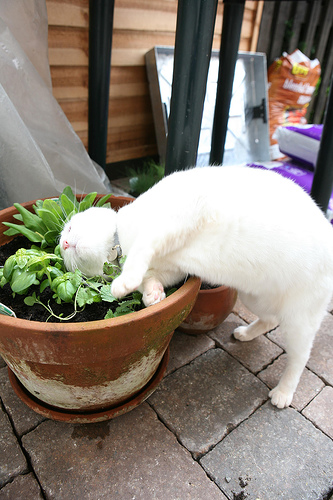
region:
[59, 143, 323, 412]
this is a cat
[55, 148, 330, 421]
the cat is white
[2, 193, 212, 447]
this is a potted plant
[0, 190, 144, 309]
the plant is green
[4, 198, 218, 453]
pot it terra cotta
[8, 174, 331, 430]
cat leaning on plant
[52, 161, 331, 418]
white cat with head in pot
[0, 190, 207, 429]
large terracotta flower pot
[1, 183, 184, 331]
green plants in flower pot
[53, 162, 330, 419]
cat rubbing head in plants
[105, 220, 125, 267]
gray collar on cat neck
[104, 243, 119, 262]
identification tag on collar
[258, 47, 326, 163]
orange bag of potting soil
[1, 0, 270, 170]
wood slat building siding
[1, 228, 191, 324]
soil in large pot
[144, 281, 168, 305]
pink cat toes on forepaw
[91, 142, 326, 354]
a white cat wearing a collar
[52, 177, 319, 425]
a white cat that is outside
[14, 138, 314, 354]
a white cat in a pot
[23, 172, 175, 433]
a pot with a plant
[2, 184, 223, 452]
a plant in a pot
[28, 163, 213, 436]
a plant that is outside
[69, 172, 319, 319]
a cat wearing a collar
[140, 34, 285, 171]
a pan that is outside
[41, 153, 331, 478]
a cat on a sidewalk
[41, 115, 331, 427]
The white cat is rubbing in the plants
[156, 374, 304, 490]
The patio has bricks on it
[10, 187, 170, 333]
There are plants in the flower pot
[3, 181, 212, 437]
The pot is made of clay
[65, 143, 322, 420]
The cat is completely white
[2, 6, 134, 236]
There is a plastic cover near the pot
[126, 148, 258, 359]
A smaller pot sits next to the cat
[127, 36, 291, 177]
A metal lid is leaned up against the wall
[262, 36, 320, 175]
A bag of soil is in the distance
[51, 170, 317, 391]
the cat is white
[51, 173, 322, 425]
the cat is white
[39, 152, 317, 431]
the cat is white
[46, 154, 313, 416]
the cat is white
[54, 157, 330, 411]
the cat is white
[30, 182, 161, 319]
cat's head on the plant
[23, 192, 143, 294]
cat's head on the plant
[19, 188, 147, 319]
cat's head on the plant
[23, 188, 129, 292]
cat's head on the plant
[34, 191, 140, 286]
cat's head on the plant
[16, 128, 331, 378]
A white short hair cat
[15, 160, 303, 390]
a cat loving a plant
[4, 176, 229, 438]
a potted green plant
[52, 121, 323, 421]
a cat only standing on hind feet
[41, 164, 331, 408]
Cat with his head in a planter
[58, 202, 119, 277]
White head of a cat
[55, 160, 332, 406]
an all white cat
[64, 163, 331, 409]
a cat standing on bricks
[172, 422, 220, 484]
spaces between ground bricks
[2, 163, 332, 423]
a cat rubbing on a plant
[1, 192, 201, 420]
green plants growing in a pot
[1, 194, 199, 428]
a planting pot and saucer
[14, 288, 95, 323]
black soil in a pot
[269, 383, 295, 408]
white fur on a paw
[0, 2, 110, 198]
semi transparent plastic sheeting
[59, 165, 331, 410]
the cat is white